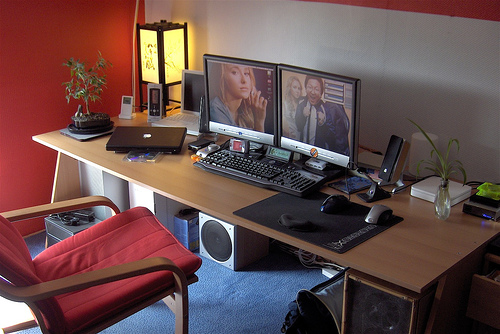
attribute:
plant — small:
[407, 113, 473, 190]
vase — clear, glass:
[434, 185, 452, 218]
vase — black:
[72, 124, 109, 133]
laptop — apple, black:
[109, 114, 186, 157]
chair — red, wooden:
[9, 192, 178, 310]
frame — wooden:
[76, 252, 188, 292]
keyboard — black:
[219, 151, 255, 173]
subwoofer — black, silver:
[381, 117, 408, 187]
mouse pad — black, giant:
[273, 195, 310, 213]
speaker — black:
[199, 98, 207, 135]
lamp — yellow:
[136, 12, 188, 81]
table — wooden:
[145, 170, 176, 184]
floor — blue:
[234, 282, 261, 317]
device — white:
[120, 186, 148, 208]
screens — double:
[215, 61, 352, 147]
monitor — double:
[209, 62, 266, 132]